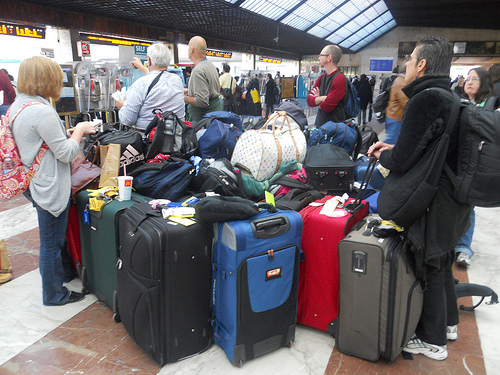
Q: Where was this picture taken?
A: Airport.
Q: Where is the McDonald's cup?
A: On top of green luggage.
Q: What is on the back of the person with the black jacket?
A: Backpack.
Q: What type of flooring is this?
A: Tile.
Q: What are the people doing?
A: Waiting with luggage.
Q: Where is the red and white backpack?
A: Left Side.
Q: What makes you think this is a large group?
A: All the luggage.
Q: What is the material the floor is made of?
A: Tile.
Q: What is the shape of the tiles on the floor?
A: Square.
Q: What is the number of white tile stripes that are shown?
A: 4.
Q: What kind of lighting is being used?
A: Fluorescent.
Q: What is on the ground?
A: Luggage.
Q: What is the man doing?
A: Standing.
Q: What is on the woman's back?
A: A backpack.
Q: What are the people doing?
A: Waiting.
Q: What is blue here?
A: Suitcases.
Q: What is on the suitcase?
A: A cup.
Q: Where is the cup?
A: On the suitcase.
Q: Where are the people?
A: Airport.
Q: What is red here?
A: Suitcase.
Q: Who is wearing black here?
A: The man.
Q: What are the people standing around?
A: Luggage.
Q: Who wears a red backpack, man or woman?
A: Woman.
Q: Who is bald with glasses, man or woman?
A: Man.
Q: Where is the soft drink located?
A: On a suitcase.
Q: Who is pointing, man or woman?
A: Man.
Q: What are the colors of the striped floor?
A: Brown and white.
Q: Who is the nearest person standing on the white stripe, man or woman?
A: Woman.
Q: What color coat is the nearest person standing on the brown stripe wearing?
A: Black.